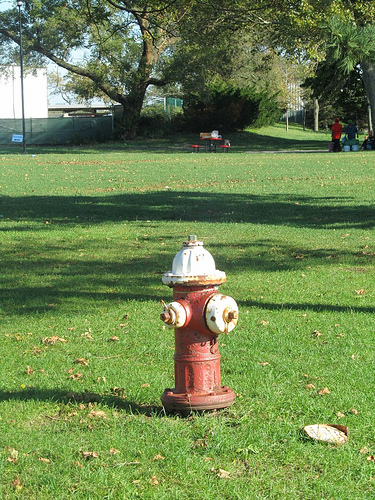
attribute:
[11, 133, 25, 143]
sign — white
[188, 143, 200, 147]
seat — red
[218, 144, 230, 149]
seat — red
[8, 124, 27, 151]
sign — white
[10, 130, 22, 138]
letters — black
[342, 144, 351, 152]
bucket — white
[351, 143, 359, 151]
bucket — white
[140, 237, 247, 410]
hydrant — red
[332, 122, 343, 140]
shirt — red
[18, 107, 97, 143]
fence — green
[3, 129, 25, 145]
sign — white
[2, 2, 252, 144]
tree — big, oak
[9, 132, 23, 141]
sign — direction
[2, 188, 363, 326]
shadow — tree, large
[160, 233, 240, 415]
hydrant — for Fire, old, fire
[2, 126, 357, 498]
grass — green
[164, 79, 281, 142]
bush — green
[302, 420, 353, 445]
paper — piece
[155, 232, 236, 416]
hydrant — fire, red, white, yellow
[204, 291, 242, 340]
plug — yellow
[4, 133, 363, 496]
field — green, grassy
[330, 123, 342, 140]
jacket — red